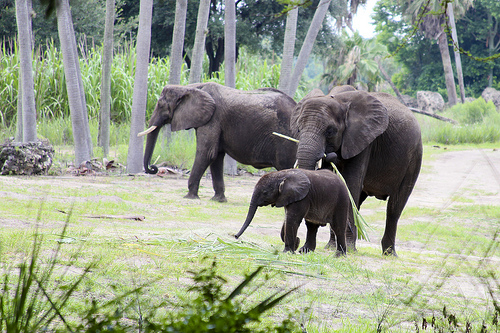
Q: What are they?
A: Elephants.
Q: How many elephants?
A: 3.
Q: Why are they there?
A: Walking.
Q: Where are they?
A: Field.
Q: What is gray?
A: The elephants.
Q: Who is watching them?
A: People.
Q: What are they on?
A: Grass.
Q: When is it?
A: Day time.